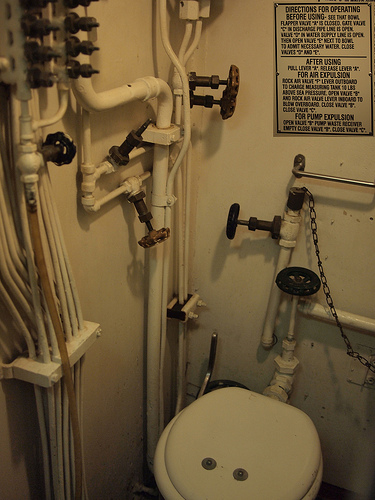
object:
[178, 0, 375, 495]
wall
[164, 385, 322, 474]
lid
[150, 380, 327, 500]
toilet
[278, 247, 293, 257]
pipes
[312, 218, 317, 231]
wires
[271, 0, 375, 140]
sign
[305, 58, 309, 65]
letters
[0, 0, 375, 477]
plumbing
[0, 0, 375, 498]
bathroom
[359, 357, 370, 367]
links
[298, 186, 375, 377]
chain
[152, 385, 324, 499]
seat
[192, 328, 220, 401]
handle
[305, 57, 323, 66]
word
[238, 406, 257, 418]
part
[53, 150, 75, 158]
part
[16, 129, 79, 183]
bolt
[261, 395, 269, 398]
edge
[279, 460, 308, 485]
part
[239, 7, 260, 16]
part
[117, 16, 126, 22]
part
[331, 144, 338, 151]
part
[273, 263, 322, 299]
sink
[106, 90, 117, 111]
piipes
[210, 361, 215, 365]
metal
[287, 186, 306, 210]
turn off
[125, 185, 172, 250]
knobs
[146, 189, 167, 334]
pipe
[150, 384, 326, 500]
flush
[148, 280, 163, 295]
pipe lines